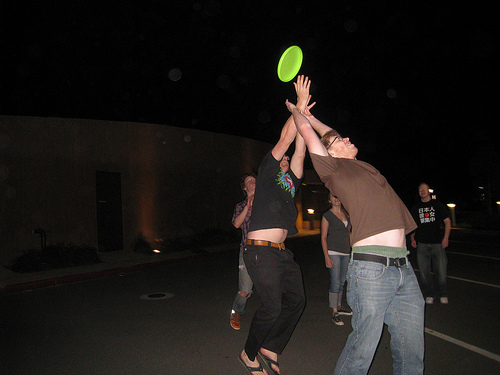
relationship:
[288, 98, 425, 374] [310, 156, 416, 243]
man wearing shirt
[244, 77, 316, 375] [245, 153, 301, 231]
man wearing shirt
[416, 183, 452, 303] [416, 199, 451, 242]
man wearing shirt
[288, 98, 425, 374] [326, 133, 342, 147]
man wearing glasses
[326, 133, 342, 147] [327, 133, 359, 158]
glasses on face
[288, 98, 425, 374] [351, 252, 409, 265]
man wearing belt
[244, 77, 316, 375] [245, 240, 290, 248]
man wearing belt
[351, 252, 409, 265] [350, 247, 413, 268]
belt around waist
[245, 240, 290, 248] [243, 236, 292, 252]
belt around waist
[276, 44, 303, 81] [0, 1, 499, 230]
frisbee in air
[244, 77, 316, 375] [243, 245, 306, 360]
man wearing pants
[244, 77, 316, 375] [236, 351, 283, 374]
man wearing flip flops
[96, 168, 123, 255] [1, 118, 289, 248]
door on building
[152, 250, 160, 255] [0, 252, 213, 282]
light on sidewalk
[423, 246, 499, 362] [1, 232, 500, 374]
lines on ground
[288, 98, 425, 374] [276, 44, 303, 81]
man playing frisbee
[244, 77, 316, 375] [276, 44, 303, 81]
man playing frisbee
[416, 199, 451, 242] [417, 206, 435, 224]
shirt has writing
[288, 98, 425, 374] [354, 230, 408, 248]
man showing belly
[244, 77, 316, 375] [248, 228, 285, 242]
man showing belly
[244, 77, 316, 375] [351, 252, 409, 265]
man wearing belt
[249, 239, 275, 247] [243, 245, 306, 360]
loops in pants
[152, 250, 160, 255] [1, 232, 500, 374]
light on ground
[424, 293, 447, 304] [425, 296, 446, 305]
sneakers on feet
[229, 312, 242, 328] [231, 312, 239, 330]
shoe on foot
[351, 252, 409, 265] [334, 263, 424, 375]
belt on jeans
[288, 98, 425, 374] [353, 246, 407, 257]
man wearing underwear